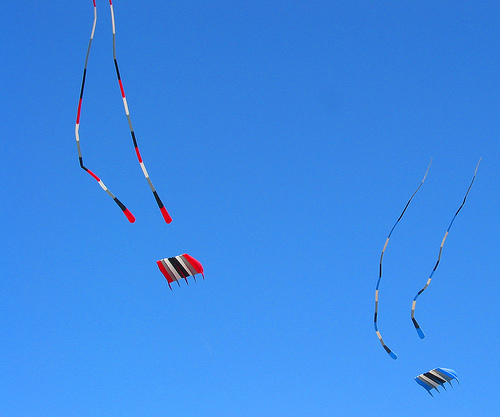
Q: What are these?
A: Kites.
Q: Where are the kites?
A: In the sky.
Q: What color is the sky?
A: Blue.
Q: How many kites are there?
A: Two.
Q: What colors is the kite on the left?
A: Red, white, grey, black.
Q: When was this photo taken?
A: During the day.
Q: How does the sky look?
A: Clear.